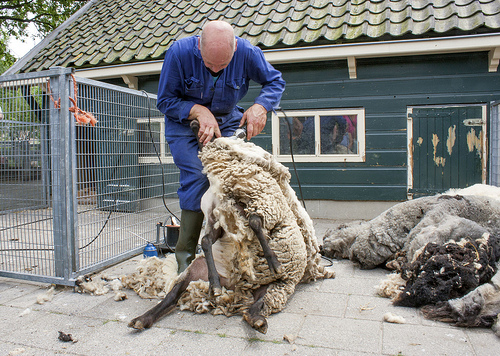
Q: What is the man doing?
A: Shaving a sheep.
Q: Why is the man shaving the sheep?
A: To get wool.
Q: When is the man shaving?
A: Right now.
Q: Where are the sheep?
A: Their outside.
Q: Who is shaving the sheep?
A: A man.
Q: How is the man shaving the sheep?
A: With a razor.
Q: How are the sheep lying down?
A: On their belly.